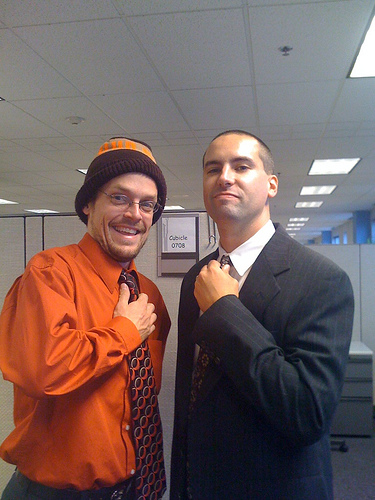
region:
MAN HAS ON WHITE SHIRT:
[241, 246, 248, 266]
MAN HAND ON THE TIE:
[220, 256, 231, 271]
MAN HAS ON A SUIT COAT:
[313, 287, 343, 315]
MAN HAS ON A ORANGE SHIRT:
[49, 411, 88, 442]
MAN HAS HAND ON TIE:
[122, 291, 149, 322]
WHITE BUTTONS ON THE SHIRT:
[124, 426, 131, 432]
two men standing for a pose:
[17, 147, 351, 499]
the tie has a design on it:
[78, 247, 176, 485]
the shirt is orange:
[4, 233, 168, 468]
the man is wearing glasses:
[78, 166, 166, 225]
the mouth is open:
[106, 215, 146, 241]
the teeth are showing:
[89, 220, 149, 244]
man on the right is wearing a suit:
[146, 215, 353, 476]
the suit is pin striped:
[145, 231, 349, 492]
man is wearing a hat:
[57, 130, 170, 240]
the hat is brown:
[42, 118, 180, 233]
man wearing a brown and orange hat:
[76, 136, 164, 231]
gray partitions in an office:
[1, 214, 217, 496]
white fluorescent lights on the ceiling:
[286, 157, 362, 266]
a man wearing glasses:
[98, 186, 162, 214]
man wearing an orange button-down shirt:
[0, 233, 170, 490]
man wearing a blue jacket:
[171, 220, 356, 496]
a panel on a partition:
[159, 213, 198, 253]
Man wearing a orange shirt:
[0, 144, 176, 499]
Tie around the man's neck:
[102, 260, 171, 491]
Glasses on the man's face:
[105, 188, 166, 215]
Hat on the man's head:
[65, 135, 169, 227]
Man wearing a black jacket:
[166, 124, 351, 499]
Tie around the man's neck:
[187, 248, 241, 406]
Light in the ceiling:
[307, 152, 362, 181]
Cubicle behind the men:
[0, 203, 237, 499]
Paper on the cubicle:
[145, 209, 201, 282]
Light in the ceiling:
[291, 197, 324, 215]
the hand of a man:
[114, 293, 151, 333]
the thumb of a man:
[114, 278, 135, 306]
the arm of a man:
[27, 269, 152, 395]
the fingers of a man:
[141, 298, 166, 324]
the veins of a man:
[114, 301, 152, 339]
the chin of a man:
[105, 240, 129, 263]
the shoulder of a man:
[18, 238, 101, 282]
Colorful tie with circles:
[117, 270, 168, 496]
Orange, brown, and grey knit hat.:
[72, 132, 167, 224]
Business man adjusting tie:
[170, 118, 343, 493]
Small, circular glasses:
[92, 182, 167, 214]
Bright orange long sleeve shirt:
[0, 230, 172, 490]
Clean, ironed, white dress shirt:
[188, 217, 274, 406]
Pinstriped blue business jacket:
[169, 220, 356, 495]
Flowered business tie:
[187, 250, 232, 423]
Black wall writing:
[162, 229, 190, 246]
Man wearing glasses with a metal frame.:
[83, 170, 168, 225]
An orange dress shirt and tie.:
[2, 228, 175, 498]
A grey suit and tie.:
[170, 226, 363, 498]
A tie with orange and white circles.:
[118, 265, 174, 498]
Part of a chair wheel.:
[319, 430, 352, 457]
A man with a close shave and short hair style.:
[192, 126, 286, 239]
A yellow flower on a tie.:
[194, 348, 213, 370]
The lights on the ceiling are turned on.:
[278, 146, 364, 240]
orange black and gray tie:
[108, 265, 173, 490]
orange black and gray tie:
[113, 261, 170, 491]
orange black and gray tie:
[109, 260, 177, 495]